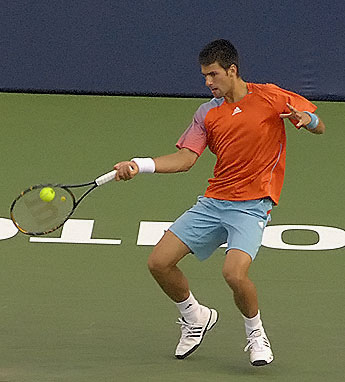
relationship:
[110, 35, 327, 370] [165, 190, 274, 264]
man in shorts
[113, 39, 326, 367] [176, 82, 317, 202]
man in orange shirt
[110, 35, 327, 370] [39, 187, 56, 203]
man in ball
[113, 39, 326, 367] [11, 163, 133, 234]
man in racket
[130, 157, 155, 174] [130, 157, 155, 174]
band on band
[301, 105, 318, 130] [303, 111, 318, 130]
sweatband on sweatband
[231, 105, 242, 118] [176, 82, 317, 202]
logo on orange shirt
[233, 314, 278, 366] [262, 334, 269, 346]
shoes with lines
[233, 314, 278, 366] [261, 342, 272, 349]
shoes with lines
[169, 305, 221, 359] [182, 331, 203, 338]
shoes with lines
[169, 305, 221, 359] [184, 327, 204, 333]
shoes with lines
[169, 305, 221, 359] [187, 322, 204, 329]
shoes with lines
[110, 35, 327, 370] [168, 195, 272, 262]
man with shorts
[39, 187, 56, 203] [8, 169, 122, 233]
ball on racket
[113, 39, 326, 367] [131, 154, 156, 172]
man wearing wristband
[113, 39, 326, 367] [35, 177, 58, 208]
man hitting ball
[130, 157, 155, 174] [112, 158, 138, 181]
band on hand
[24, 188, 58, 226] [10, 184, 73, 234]
strings in strings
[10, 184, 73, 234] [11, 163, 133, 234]
strings of racket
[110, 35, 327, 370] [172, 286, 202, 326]
man wears sock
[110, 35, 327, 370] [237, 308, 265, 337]
man wears sock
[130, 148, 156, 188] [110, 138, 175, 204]
band on wrist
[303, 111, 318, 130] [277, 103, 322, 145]
sweatband on hand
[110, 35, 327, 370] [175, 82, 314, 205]
man wearing orange shirt